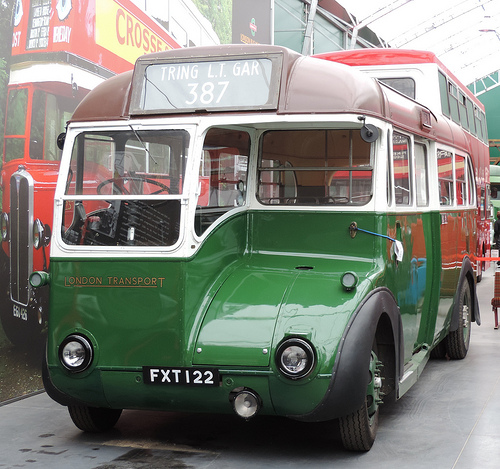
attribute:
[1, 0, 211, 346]
bus — large, red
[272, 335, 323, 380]
head light — matching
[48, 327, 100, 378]
head light — matching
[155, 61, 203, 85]
tring — white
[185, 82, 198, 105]
number — 3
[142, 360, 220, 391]
letters — white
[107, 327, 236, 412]
license plate — black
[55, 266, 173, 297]
london transport — gold, written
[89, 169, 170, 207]
steering wheel — black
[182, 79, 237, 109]
number — 387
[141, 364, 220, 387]
license plate — black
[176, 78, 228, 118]
number — 387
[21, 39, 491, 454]
bus — 387, vintage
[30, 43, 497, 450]
vehicle — green